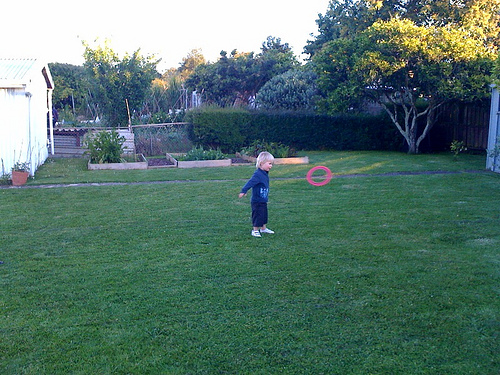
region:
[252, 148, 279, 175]
the head of a boy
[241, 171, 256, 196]
the arm of a boy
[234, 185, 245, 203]
the hand of a boy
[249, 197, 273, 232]
the legs of a boy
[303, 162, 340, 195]
a pink disc in the sky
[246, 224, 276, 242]
a pair of white shoes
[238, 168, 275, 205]
a blue shirt on the boy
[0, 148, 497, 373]
a grassy green lawn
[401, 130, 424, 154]
the trunk of a tree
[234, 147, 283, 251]
a boy on the grass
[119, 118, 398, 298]
The child is outside.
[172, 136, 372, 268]
The child is playing.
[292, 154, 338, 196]
A hoop is airborne.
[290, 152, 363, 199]
The hoop is pink.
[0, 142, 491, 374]
The child is on a lawn.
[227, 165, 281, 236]
The child is dressed in blue.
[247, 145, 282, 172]
The child has blonde hair.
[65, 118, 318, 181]
A garden is on the lawn.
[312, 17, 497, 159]
A tree is on the lawn.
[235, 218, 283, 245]
The child's shoes are white.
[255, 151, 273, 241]
young child playing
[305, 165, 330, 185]
red ring in air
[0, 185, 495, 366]
big backyard with green grass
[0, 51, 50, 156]
white shed in backyard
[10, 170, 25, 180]
red pot in front of white shed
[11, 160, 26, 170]
plant in red pot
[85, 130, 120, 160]
bush in planter behind child playing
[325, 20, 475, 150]
medium-sized tree in backyard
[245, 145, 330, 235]
little child throwing red frisbee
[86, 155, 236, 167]
wooden planters in backyard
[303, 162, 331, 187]
a red frisbee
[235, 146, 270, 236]
a little boy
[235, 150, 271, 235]
a little boy wearing a blue shirt and white shoes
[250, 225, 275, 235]
white shoes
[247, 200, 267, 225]
blue shorts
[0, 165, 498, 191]
a grey sidewalk in the green grass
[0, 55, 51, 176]
a white shed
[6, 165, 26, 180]
a reddish brownish colored terracotta plant holder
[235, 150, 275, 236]
a little boy with blonde hair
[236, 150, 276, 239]
a little boy with blonde hair wearing a blue shirt and blue shorts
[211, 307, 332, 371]
The grass is green.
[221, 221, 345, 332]
The grass is green.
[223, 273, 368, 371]
The grass is green.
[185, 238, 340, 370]
The grass is green.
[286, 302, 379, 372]
The grass is green.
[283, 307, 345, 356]
The grass is green.